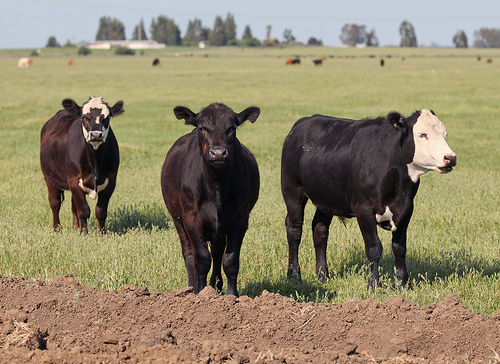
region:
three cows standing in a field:
[38, 90, 460, 291]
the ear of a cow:
[58, 93, 85, 117]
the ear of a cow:
[111, 97, 126, 119]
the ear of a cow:
[171, 101, 197, 127]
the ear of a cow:
[236, 102, 260, 128]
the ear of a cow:
[382, 105, 404, 132]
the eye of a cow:
[416, 129, 429, 144]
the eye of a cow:
[224, 120, 236, 138]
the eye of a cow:
[195, 122, 214, 136]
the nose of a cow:
[84, 127, 109, 145]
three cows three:
[23, 84, 480, 316]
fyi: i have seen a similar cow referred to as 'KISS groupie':
[30, 80, 135, 245]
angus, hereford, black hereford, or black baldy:
[22, 77, 462, 307]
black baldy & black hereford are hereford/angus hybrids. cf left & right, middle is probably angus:
[25, 85, 470, 315]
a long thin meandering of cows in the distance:
[9, 50, 495, 73]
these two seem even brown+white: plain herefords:
[12, 52, 79, 77]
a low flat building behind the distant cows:
[67, 38, 214, 56]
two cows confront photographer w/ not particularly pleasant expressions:
[24, 81, 271, 308]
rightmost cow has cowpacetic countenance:
[267, 96, 468, 306]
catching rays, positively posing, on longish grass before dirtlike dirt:
[28, 79, 468, 309]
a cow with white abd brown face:
[34, 66, 147, 237]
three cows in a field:
[20, 45, 486, 305]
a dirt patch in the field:
[24, 266, 335, 360]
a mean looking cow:
[150, 78, 270, 286]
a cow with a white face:
[275, 87, 472, 290]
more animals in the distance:
[18, 51, 498, 79]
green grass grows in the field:
[20, 208, 497, 296]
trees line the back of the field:
[64, 5, 481, 91]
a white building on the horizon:
[75, 29, 186, 66]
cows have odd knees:
[71, 176, 121, 228]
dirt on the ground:
[7, 280, 487, 359]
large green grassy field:
[0, 52, 492, 316]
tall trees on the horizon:
[71, 12, 495, 50]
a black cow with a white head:
[274, 97, 458, 299]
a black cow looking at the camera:
[159, 95, 266, 308]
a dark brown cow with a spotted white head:
[33, 93, 135, 238]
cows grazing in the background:
[19, 49, 497, 71]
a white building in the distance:
[88, 38, 166, 49]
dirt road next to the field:
[1, 300, 488, 362]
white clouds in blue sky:
[24, 2, 47, 27]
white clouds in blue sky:
[69, 18, 120, 51]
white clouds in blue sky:
[248, 16, 278, 33]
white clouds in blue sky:
[287, 7, 351, 51]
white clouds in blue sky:
[373, 6, 414, 48]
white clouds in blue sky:
[385, 4, 429, 41]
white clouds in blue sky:
[147, 20, 222, 35]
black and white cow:
[45, 87, 131, 222]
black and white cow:
[160, 106, 265, 283]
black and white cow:
[267, 91, 454, 257]